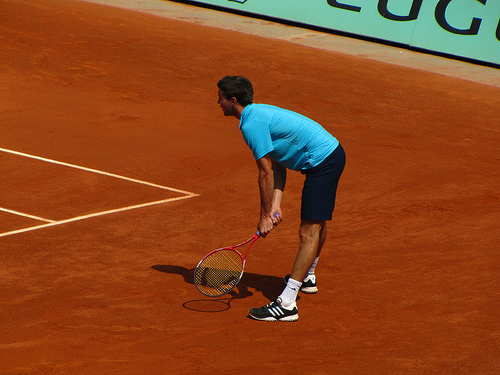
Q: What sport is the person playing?
A: Tennis.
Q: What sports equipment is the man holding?
A: Tennis racquet.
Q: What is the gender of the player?
A: Male.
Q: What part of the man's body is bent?
A: Waist.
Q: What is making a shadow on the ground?
A: Tennis player.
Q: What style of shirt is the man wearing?
A: Polo.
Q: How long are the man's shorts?
A: Knee length.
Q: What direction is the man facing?
A: Left.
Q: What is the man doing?
A: Playing tennis.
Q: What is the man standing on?
A: Tennis court.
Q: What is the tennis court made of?
A: Dirt.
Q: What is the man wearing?
A: Shirt.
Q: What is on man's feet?
A: Tennis Shoes.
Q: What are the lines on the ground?
A: Chalk.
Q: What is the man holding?
A: Racket.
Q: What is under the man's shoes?
A: Socks.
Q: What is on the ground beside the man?
A: Shadow.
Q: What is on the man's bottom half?
A: Shorts.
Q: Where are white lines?
A: On court.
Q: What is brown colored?
A: Tennis court.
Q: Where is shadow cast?
A: Under man.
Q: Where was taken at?
A: Tennis court.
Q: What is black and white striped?
A: Man's shoes.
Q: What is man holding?
A: Racket.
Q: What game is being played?
A: Tennis.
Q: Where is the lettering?
A: On teal sign.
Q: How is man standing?
A: Bent over.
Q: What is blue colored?
A: Shirt.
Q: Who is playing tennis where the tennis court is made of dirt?
A: Person in blue shirt.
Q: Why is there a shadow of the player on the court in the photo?
A: Because of the sun.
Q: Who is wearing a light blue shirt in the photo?
A: Player with black short.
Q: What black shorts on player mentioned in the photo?
A: Person with black and white shoes.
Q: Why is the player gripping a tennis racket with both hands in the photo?
A: Better hit the ball.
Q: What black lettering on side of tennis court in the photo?
A: In back of player.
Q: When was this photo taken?
A: During the day.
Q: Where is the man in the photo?
A: On a tennis court.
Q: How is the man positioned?
A: Bending at the waist.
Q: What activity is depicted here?
A: Tennis.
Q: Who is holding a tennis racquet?
A: The man.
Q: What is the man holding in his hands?
A: A tennis racquet.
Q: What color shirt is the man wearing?
A: Light blue.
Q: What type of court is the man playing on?
A: Clay court.